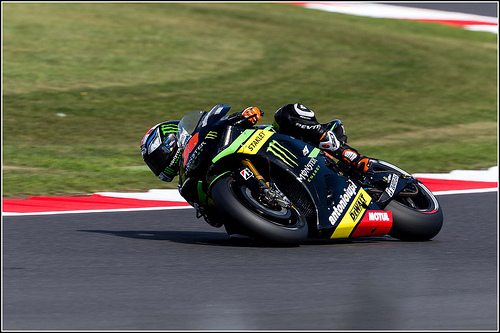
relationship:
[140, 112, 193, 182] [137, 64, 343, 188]
helmet on motorcyclist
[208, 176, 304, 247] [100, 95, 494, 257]
tire on motorcycle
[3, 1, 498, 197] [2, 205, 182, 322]
grass inside track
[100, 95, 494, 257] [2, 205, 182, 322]
motorcycle on track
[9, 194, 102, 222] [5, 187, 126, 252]
red on side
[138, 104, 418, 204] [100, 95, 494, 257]
man riding bike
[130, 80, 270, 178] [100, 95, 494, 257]
man riding motorcycle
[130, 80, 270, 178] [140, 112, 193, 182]
man wearing helmet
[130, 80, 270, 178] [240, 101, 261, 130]
man wearing glove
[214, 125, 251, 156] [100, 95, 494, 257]
sticker on motorcycle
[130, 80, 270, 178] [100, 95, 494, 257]
someone riding motorcycle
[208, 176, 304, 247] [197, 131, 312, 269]
wheel in front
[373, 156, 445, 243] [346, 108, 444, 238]
wheel in back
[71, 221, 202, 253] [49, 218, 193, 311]
shadow on ground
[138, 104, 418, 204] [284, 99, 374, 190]
man has leg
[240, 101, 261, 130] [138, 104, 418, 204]
glove on man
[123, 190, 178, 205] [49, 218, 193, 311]
white on ground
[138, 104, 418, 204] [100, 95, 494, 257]
man leaning on motorcycle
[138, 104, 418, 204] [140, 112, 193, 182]
man wearing helmet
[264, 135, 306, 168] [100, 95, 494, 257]
logo on motorcycle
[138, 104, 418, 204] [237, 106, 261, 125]
man wearing glove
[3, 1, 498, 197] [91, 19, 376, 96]
grass in infield